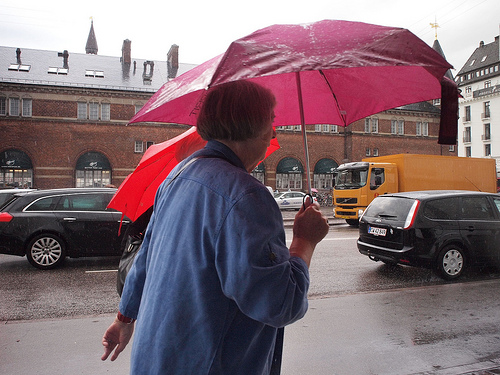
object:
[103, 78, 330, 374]
person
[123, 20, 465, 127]
umbrella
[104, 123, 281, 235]
umbrella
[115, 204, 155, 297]
person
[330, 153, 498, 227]
truck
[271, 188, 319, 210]
car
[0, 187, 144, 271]
car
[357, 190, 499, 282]
car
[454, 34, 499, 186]
building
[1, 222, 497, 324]
road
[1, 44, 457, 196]
building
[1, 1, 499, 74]
sky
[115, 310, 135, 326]
watch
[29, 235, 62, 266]
rims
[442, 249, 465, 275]
rims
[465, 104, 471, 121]
window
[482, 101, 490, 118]
window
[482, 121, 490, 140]
window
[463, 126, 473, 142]
window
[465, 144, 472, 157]
window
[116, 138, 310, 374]
shirt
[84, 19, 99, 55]
steeple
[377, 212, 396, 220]
wiper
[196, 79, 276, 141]
hair